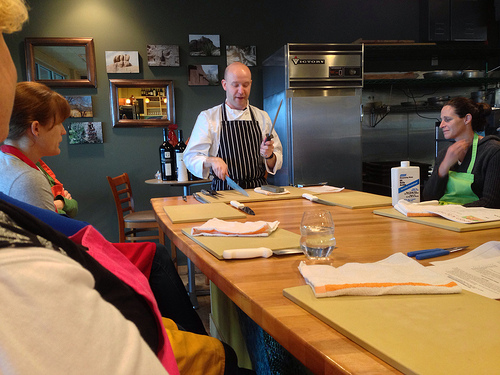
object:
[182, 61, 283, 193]
man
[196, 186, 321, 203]
board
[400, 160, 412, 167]
top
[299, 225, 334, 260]
water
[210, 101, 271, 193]
apron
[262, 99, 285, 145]
knife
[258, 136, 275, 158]
hand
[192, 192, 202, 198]
handle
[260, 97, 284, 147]
blade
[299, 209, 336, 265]
bottle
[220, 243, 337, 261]
knife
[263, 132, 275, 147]
handle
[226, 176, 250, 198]
knife blade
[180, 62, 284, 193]
chef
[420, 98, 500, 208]
woman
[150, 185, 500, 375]
table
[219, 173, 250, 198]
knife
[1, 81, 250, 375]
woman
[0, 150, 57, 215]
shirt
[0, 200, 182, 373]
apron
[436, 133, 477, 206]
apron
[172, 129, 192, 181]
bottle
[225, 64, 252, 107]
face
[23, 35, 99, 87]
frame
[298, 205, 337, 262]
glass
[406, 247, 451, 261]
handle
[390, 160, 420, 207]
bottle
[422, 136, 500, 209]
shirt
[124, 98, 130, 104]
lights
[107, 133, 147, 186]
wall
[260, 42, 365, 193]
appliance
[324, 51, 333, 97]
lights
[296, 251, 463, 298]
towel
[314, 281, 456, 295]
stripe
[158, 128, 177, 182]
bottle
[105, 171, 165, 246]
chair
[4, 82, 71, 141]
hair